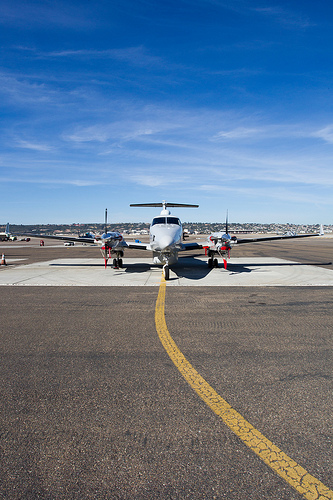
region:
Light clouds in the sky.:
[42, 101, 324, 194]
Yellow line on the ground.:
[160, 340, 297, 480]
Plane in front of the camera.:
[16, 191, 324, 306]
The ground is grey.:
[30, 333, 137, 438]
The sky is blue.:
[171, 10, 289, 76]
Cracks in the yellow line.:
[221, 417, 309, 482]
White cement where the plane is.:
[24, 248, 324, 288]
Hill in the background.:
[14, 218, 325, 238]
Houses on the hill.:
[247, 220, 330, 231]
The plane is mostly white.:
[36, 200, 319, 261]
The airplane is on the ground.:
[0, 189, 327, 288]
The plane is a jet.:
[3, 195, 324, 280]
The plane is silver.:
[3, 194, 324, 276]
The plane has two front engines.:
[83, 206, 251, 282]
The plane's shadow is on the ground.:
[43, 256, 311, 280]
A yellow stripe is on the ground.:
[152, 281, 330, 498]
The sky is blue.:
[0, 0, 329, 121]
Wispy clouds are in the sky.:
[0, 99, 331, 194]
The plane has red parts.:
[89, 235, 235, 272]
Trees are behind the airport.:
[0, 217, 311, 241]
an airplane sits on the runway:
[0, 191, 328, 291]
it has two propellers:
[91, 195, 250, 284]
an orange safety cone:
[0, 248, 9, 271]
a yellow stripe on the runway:
[176, 285, 312, 495]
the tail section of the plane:
[123, 191, 203, 220]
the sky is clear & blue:
[104, 147, 276, 189]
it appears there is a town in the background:
[18, 223, 311, 239]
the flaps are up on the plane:
[2, 219, 328, 252]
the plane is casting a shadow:
[44, 247, 330, 289]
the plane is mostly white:
[99, 184, 242, 281]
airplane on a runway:
[62, 171, 329, 281]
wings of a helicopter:
[22, 209, 129, 273]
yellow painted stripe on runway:
[123, 319, 315, 484]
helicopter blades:
[102, 182, 204, 216]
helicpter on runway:
[3, 164, 324, 311]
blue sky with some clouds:
[79, 67, 291, 181]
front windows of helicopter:
[151, 213, 183, 231]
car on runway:
[60, 240, 76, 248]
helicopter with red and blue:
[3, 177, 323, 300]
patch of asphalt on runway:
[38, 335, 155, 463]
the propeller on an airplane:
[95, 201, 115, 279]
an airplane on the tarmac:
[1, 196, 319, 276]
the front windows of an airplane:
[149, 211, 183, 226]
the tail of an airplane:
[128, 198, 202, 213]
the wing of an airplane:
[182, 227, 320, 260]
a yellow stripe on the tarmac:
[148, 271, 331, 498]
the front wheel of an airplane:
[157, 259, 174, 280]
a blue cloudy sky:
[0, 0, 330, 222]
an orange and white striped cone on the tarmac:
[0, 248, 12, 267]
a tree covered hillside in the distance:
[0, 223, 61, 235]